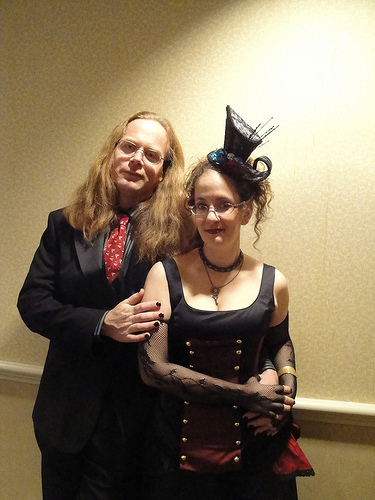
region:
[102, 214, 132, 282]
The tie is red.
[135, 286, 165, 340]
His nails are black.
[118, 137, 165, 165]
The man wears glasses.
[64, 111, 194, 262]
The man's hair is blonde.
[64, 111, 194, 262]
The man's hair is long.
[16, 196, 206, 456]
The jacket is black.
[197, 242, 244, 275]
The choker is black.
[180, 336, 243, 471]
The top has two rows of brass buttons.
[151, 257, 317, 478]
The woman wears a red and black top.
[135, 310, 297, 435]
The woman wear's fishnet gloves.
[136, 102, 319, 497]
A woman in a black and red dress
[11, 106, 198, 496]
A man in a black jacket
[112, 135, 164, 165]
A pair of glasses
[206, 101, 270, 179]
A small black hat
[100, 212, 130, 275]
A red and white tie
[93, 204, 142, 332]
A black and grey striped shirt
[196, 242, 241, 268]
A chain shaped choker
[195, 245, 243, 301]
A black necklace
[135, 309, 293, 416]
some black fishnet sleeves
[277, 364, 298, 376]
a gold colored armband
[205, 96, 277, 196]
decorative hat on a woman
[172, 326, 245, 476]
brass buttons on a woman's shirt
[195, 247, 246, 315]
two necklaces on a woman's neck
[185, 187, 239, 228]
eye glasses on a woman's face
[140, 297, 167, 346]
black fingernails on a man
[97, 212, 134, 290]
red tie on a man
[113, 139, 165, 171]
eye glasses on a man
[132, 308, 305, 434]
lace fingerless gloves on a woman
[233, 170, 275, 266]
curly tendrils of a woman's hair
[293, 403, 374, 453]
shadow of moulding on the wall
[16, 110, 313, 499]
man with his arm around a woman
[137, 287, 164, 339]
the man's black finger nails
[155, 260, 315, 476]
the woman's black and red top with gold buttons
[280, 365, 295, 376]
yellow wrist band on woman's arm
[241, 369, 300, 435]
the couple holding hands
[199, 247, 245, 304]
the woman's necklaces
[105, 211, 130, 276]
the man's red necktie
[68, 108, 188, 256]
the man's long red hair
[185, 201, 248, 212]
the woman's glasses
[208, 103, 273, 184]
a small hat on the woman's head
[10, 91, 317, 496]
a couple wearing a custom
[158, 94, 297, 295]
woman has a small hat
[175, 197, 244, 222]
glasses on a face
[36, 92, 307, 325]
the couple is blonde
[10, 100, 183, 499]
man wears a black suit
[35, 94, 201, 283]
man has long hair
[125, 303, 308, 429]
a pair of black gloves on arms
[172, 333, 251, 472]
yellow buttons on dress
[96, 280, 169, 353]
a hand with nail polish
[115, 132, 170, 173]
glasses on face